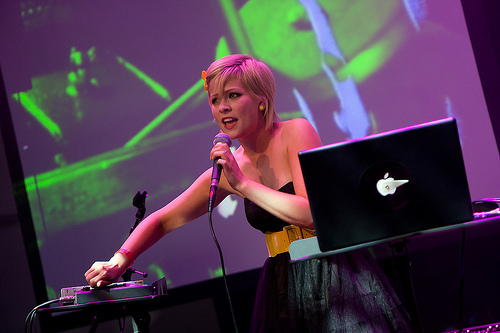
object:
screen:
[0, 0, 500, 317]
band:
[114, 248, 134, 263]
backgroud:
[0, 0, 500, 280]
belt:
[263, 224, 317, 259]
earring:
[259, 105, 264, 110]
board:
[33, 277, 171, 325]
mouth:
[221, 116, 239, 130]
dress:
[240, 180, 416, 333]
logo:
[375, 173, 410, 197]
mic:
[206, 132, 234, 212]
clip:
[201, 70, 210, 92]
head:
[201, 54, 278, 141]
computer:
[295, 115, 476, 254]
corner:
[445, 116, 456, 123]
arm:
[101, 163, 231, 261]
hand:
[82, 258, 125, 289]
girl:
[81, 54, 411, 333]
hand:
[207, 141, 246, 191]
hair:
[205, 53, 278, 131]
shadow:
[256, 154, 280, 193]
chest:
[240, 180, 302, 234]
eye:
[228, 92, 244, 100]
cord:
[207, 188, 240, 333]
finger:
[216, 158, 229, 171]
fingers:
[211, 150, 230, 162]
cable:
[21, 295, 68, 333]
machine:
[56, 278, 156, 307]